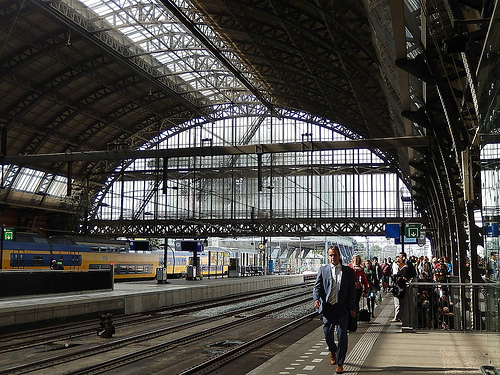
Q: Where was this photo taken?
A: Subway station.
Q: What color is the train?
A: Blue and yellow.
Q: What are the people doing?
A: Waiting for the train.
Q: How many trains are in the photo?
A: 1.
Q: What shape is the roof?
A: Semi-circle.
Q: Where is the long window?
A: In the domed ceiling.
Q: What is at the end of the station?
A: A large window.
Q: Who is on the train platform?
A: People are on the platform.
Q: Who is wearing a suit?
A: The man walking.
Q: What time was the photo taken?
A: Photo was taken during the day.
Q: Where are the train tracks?
A: The train tracks are in the photo.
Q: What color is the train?
A: The train is yellow and blue.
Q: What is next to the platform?
A: The train is next to the platform.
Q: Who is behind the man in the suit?
A: A woman is behind the man.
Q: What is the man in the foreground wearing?
A: Suit and tie.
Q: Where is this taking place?
A: Train station.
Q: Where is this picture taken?
A: A train station.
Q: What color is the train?
A: Yellow.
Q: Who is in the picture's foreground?
A: A man.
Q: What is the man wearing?
A: A suit.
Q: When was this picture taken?
A: Daytime.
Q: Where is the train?
A: On the train tracks.